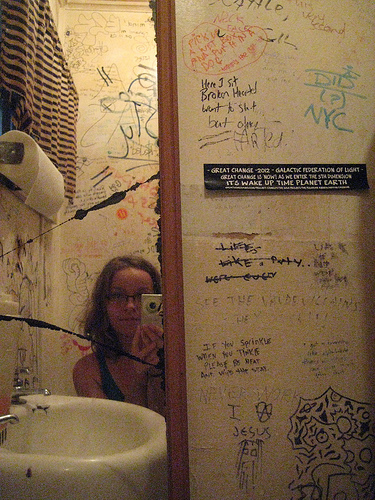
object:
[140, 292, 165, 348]
camera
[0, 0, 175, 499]
mirror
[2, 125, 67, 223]
paper towels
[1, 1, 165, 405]
wall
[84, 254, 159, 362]
hair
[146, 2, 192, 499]
wood frame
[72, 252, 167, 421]
girl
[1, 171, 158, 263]
cracks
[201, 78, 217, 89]
word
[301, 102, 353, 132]
word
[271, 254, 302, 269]
word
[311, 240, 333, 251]
word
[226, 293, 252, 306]
word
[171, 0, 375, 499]
wall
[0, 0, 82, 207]
curtain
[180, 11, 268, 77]
red ink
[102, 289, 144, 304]
eyeglasses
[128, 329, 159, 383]
hand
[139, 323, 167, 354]
hand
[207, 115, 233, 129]
words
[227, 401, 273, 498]
writing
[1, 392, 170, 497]
sink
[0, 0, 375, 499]
bathroom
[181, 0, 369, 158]
graffiti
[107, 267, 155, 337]
face